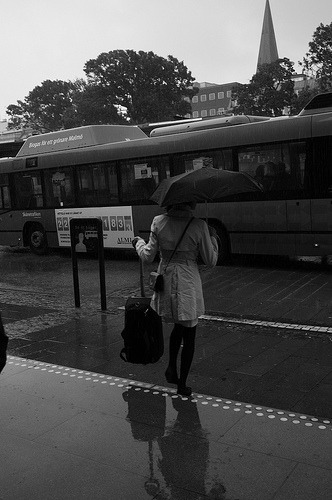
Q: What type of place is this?
A: It is a sidewalk.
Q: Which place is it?
A: It is a sidewalk.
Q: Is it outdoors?
A: Yes, it is outdoors.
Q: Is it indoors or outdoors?
A: It is outdoors.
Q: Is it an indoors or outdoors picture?
A: It is outdoors.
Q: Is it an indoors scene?
A: No, it is outdoors.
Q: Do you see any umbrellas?
A: Yes, there is an umbrella.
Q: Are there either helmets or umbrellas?
A: Yes, there is an umbrella.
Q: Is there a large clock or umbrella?
A: Yes, there is a large umbrella.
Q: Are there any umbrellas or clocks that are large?
A: Yes, the umbrella is large.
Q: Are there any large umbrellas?
A: Yes, there is a large umbrella.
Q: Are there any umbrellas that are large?
A: Yes, there is an umbrella that is large.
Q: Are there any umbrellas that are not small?
A: Yes, there is a large umbrella.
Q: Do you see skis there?
A: No, there are no skis.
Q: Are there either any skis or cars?
A: No, there are no skis or cars.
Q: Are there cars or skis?
A: No, there are no skis or cars.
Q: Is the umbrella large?
A: Yes, the umbrella is large.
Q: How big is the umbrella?
A: The umbrella is large.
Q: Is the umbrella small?
A: No, the umbrella is large.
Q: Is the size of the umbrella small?
A: No, the umbrella is large.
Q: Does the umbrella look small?
A: No, the umbrella is large.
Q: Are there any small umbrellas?
A: No, there is an umbrella but it is large.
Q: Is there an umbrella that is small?
A: No, there is an umbrella but it is large.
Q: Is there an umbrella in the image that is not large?
A: No, there is an umbrella but it is large.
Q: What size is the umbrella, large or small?
A: The umbrella is large.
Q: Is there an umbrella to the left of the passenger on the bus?
A: Yes, there is an umbrella to the left of the passenger.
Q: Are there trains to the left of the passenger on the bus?
A: No, there is an umbrella to the left of the passenger.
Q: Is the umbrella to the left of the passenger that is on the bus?
A: Yes, the umbrella is to the left of the passenger.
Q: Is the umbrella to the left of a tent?
A: No, the umbrella is to the left of the passenger.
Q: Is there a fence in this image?
A: No, there are no fences.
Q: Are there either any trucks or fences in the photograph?
A: No, there are no fences or trucks.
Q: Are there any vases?
A: No, there are no vases.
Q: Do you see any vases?
A: No, there are no vases.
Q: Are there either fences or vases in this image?
A: No, there are no vases or fences.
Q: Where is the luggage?
A: The luggage is on the ground.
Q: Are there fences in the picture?
A: No, there are no fences.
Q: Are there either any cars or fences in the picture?
A: No, there are no fences or cars.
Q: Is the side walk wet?
A: Yes, the side walk is wet.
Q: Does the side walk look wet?
A: Yes, the side walk is wet.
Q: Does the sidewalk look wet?
A: Yes, the sidewalk is wet.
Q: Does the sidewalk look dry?
A: No, the sidewalk is wet.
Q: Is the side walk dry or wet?
A: The side walk is wet.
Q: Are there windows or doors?
A: Yes, there is a window.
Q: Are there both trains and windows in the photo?
A: No, there is a window but no trains.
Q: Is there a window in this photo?
A: Yes, there is a window.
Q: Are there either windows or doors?
A: Yes, there is a window.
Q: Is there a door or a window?
A: Yes, there is a window.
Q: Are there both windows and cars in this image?
A: No, there is a window but no cars.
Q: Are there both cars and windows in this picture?
A: No, there is a window but no cars.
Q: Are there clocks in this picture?
A: No, there are no clocks.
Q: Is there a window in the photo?
A: Yes, there is a window.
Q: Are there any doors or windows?
A: Yes, there is a window.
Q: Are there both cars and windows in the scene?
A: No, there is a window but no cars.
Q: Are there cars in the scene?
A: No, there are no cars.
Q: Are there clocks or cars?
A: No, there are no cars or clocks.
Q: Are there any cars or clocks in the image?
A: No, there are no cars or clocks.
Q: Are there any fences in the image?
A: No, there are no fences.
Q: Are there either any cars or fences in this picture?
A: No, there are no fences or cars.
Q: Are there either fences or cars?
A: No, there are no fences or cars.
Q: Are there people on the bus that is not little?
A: Yes, there are people on the bus.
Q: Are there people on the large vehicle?
A: Yes, there are people on the bus.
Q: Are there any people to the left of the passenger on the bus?
A: Yes, there are people to the left of the passenger.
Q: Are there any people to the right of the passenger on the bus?
A: No, the people are to the left of the passenger.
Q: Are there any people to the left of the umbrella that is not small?
A: No, the people are to the right of the umbrella.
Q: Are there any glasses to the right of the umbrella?
A: No, there are people to the right of the umbrella.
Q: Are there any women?
A: Yes, there is a woman.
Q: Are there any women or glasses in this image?
A: Yes, there is a woman.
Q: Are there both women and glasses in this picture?
A: No, there is a woman but no glasses.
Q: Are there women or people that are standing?
A: Yes, the woman is standing.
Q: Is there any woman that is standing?
A: Yes, there is a woman that is standing.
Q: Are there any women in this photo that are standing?
A: Yes, there is a woman that is standing.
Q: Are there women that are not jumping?
A: Yes, there is a woman that is standing.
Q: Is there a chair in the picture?
A: No, there are no chairs.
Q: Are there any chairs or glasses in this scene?
A: No, there are no chairs or glasses.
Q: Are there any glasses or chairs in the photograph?
A: No, there are no chairs or glasses.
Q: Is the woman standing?
A: Yes, the woman is standing.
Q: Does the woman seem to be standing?
A: Yes, the woman is standing.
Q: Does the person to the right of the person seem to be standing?
A: Yes, the woman is standing.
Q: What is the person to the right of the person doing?
A: The woman is standing.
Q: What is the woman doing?
A: The woman is standing.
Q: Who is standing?
A: The woman is standing.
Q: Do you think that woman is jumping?
A: No, the woman is standing.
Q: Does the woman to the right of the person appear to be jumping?
A: No, the woman is standing.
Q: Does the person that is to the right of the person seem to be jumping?
A: No, the woman is standing.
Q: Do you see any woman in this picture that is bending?
A: No, there is a woman but she is standing.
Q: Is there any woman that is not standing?
A: No, there is a woman but she is standing.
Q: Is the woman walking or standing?
A: The woman is standing.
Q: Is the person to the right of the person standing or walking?
A: The woman is standing.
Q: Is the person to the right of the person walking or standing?
A: The woman is standing.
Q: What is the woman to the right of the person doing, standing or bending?
A: The woman is standing.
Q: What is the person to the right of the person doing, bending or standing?
A: The woman is standing.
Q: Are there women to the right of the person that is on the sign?
A: Yes, there is a woman to the right of the person.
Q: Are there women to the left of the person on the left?
A: No, the woman is to the right of the person.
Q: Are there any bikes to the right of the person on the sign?
A: No, there is a woman to the right of the person.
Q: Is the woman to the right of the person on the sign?
A: Yes, the woman is to the right of the person.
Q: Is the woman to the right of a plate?
A: No, the woman is to the right of the person.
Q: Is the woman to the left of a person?
A: No, the woman is to the right of a person.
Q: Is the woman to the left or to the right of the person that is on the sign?
A: The woman is to the right of the person.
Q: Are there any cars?
A: No, there are no cars.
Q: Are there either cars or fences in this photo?
A: No, there are no cars or fences.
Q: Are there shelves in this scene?
A: No, there are no shelves.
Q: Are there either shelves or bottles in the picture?
A: No, there are no shelves or bottles.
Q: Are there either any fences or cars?
A: No, there are no cars or fences.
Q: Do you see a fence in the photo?
A: No, there are no fences.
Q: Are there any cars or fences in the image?
A: No, there are no fences or cars.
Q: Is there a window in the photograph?
A: Yes, there is a window.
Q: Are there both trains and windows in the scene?
A: No, there is a window but no trains.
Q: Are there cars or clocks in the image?
A: No, there are no cars or clocks.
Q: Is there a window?
A: Yes, there is a window.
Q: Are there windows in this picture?
A: Yes, there is a window.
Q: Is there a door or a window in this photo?
A: Yes, there is a window.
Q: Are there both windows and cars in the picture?
A: No, there is a window but no cars.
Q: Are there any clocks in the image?
A: No, there are no clocks.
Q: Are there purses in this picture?
A: Yes, there is a purse.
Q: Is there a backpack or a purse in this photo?
A: Yes, there is a purse.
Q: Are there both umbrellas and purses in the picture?
A: Yes, there are both a purse and an umbrella.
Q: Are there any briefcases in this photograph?
A: No, there are no briefcases.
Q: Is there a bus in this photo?
A: Yes, there is a bus.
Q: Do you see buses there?
A: Yes, there is a bus.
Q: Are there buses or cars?
A: Yes, there is a bus.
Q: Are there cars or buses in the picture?
A: Yes, there is a bus.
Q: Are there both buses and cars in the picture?
A: No, there is a bus but no cars.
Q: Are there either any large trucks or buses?
A: Yes, there is a large bus.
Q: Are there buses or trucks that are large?
A: Yes, the bus is large.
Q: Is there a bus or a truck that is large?
A: Yes, the bus is large.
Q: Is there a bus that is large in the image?
A: Yes, there is a large bus.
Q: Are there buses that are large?
A: Yes, there is a bus that is large.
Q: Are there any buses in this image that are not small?
A: Yes, there is a large bus.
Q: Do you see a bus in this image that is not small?
A: Yes, there is a large bus.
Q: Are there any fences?
A: No, there are no fences.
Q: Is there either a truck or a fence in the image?
A: No, there are no fences or trucks.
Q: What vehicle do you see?
A: The vehicle is a bus.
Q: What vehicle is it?
A: The vehicle is a bus.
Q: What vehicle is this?
A: This is a bus.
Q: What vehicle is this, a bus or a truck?
A: This is a bus.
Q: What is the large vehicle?
A: The vehicle is a bus.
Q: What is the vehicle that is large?
A: The vehicle is a bus.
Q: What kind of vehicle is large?
A: The vehicle is a bus.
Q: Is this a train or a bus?
A: This is a bus.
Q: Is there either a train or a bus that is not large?
A: No, there is a bus but it is large.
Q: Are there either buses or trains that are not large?
A: No, there is a bus but it is large.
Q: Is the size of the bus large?
A: Yes, the bus is large.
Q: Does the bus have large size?
A: Yes, the bus is large.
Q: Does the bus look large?
A: Yes, the bus is large.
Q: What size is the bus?
A: The bus is large.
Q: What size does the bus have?
A: The bus has large size.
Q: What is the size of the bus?
A: The bus is large.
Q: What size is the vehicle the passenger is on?
A: The bus is large.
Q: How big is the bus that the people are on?
A: The bus is large.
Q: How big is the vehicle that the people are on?
A: The bus is large.